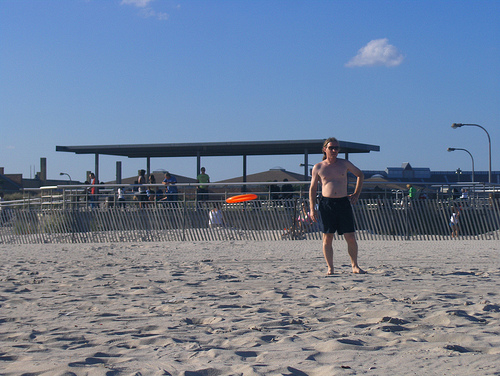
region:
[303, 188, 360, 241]
Man wearing black shorts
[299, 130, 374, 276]
Man standing on the beach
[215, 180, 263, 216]
orange Frisbee in the sky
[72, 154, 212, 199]
crowd of people standing on the boardwalk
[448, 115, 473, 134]
Street lamp on a pole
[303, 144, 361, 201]
man without a shirt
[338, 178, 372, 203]
Man with hand on his hips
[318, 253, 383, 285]
Man barefoot on the beach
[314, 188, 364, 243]
Man wearing swim trunks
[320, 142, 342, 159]
Man wearing sunglasses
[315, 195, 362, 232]
man in black shorts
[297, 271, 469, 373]
sand on the beach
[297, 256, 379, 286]
man stepping on sand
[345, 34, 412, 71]
cloud in the sky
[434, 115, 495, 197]
lights by the beach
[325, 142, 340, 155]
man wearing sunglasses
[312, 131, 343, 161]
head of the man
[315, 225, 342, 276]
leg of the man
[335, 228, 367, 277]
leg of the man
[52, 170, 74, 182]
light pole by the building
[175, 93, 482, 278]
a man on the beach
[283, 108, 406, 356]
a man on the sand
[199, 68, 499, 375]
a man standing on the beach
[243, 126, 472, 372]
a man standing on the sand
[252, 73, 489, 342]
a man wearing shorts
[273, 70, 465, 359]
a man weraing black shrots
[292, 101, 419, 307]
a man wearing sunglasses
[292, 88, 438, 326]
a man wearing glasses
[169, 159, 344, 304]
an orange freesbee in the air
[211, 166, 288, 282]
a freesbee in the air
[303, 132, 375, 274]
Man wearing black shorts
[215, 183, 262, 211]
Orange frisbee in the air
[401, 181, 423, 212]
Man wearing a green shirt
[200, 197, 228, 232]
Woman wearing a white tank top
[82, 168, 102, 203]
Man wearing a red shirt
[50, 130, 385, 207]
Canopy over the people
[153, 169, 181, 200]
Man wearing a blue shirt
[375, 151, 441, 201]
Building in the background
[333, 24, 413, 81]
White cloud in the sky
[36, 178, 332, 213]
Silver railing in front of people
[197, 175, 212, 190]
man wearing a green shirt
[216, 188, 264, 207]
Frisbee in the sky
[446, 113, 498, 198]
Street lamp on a pole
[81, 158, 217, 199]
Crowd on the boardwalk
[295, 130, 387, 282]
Man standing in the sand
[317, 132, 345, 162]
Man with blonde hair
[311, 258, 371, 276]
Man barefoot in the sand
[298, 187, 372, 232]
Man with hand on his waist